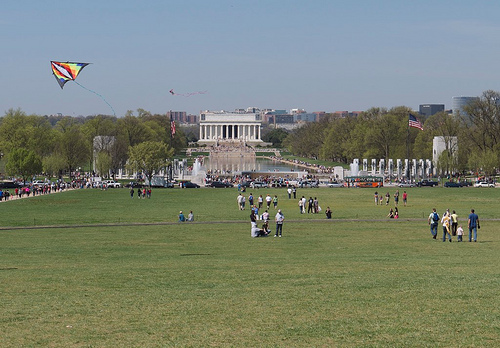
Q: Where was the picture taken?
A: It was taken at the park.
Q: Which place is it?
A: It is a park.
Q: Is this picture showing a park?
A: Yes, it is showing a park.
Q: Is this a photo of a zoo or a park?
A: It is showing a park.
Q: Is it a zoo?
A: No, it is a park.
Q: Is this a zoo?
A: No, it is a park.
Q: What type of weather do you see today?
A: It is clear.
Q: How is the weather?
A: It is clear.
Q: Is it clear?
A: Yes, it is clear.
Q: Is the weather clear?
A: Yes, it is clear.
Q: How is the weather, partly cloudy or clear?
A: It is clear.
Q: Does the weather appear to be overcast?
A: No, it is clear.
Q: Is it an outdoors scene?
A: Yes, it is outdoors.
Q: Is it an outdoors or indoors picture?
A: It is outdoors.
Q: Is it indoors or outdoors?
A: It is outdoors.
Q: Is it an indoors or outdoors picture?
A: It is outdoors.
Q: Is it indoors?
A: No, it is outdoors.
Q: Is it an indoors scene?
A: No, it is outdoors.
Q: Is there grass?
A: Yes, there is grass.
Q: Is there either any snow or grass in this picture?
A: Yes, there is grass.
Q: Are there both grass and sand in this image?
A: No, there is grass but no sand.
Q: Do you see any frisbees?
A: No, there are no frisbees.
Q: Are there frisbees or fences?
A: No, there are no frisbees or fences.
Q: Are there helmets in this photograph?
A: No, there are no helmets.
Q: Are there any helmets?
A: No, there are no helmets.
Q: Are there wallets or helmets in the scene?
A: No, there are no helmets or wallets.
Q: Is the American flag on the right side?
A: Yes, the American flag is on the right of the image.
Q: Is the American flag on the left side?
A: No, the American flag is on the right of the image.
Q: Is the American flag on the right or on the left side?
A: The American flag is on the right of the image.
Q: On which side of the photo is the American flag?
A: The American flag is on the right of the image.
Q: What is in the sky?
A: The American flag is in the sky.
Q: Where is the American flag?
A: The American flag is in the sky.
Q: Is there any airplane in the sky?
A: No, there is an American flag in the sky.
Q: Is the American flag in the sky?
A: Yes, the American flag is in the sky.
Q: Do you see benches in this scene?
A: No, there are no benches.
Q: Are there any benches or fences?
A: No, there are no benches or fences.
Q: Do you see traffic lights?
A: No, there are no traffic lights.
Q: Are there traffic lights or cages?
A: No, there are no traffic lights or cages.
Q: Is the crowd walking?
A: Yes, the crowd is walking.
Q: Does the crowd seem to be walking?
A: Yes, the crowd is walking.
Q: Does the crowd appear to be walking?
A: Yes, the crowd is walking.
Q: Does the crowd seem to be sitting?
A: No, the crowd is walking.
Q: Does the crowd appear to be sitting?
A: No, the crowd is walking.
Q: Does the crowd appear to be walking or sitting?
A: The crowd is walking.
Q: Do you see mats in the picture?
A: No, there are no mats.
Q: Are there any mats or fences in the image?
A: No, there are no mats or fences.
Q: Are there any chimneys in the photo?
A: No, there are no chimneys.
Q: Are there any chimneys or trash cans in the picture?
A: No, there are no chimneys or trash cans.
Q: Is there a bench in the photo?
A: No, there are no benches.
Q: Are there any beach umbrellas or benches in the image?
A: No, there are no benches or beach umbrellas.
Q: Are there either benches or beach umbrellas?
A: No, there are no benches or beach umbrellas.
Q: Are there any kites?
A: Yes, there is a kite.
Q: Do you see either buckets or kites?
A: Yes, there is a kite.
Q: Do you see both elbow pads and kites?
A: No, there is a kite but no elbow pads.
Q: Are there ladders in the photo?
A: No, there are no ladders.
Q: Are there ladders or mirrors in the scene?
A: No, there are no ladders or mirrors.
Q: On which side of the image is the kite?
A: The kite is on the left of the image.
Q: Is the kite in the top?
A: Yes, the kite is in the top of the image.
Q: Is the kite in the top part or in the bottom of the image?
A: The kite is in the top of the image.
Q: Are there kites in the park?
A: Yes, there is a kite in the park.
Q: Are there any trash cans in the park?
A: No, there is a kite in the park.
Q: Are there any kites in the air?
A: Yes, there is a kite in the air.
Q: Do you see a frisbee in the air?
A: No, there is a kite in the air.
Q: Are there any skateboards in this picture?
A: No, there are no skateboards.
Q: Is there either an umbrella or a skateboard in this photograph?
A: No, there are no skateboards or umbrellas.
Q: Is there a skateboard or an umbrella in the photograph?
A: No, there are no skateboards or umbrellas.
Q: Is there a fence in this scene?
A: No, there are no fences.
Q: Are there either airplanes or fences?
A: No, there are no fences or airplanes.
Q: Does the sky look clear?
A: Yes, the sky is clear.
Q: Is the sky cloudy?
A: No, the sky is clear.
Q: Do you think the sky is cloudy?
A: No, the sky is clear.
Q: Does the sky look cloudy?
A: No, the sky is clear.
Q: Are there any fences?
A: No, there are no fences.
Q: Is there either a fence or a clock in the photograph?
A: No, there are no fences or clocks.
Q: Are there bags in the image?
A: No, there are no bags.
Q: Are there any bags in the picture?
A: No, there are no bags.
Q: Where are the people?
A: The people are at the building.